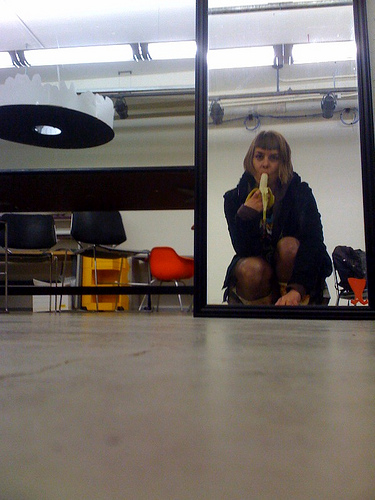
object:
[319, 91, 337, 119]
spotlight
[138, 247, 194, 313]
chair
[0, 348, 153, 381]
crack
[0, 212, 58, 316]
chair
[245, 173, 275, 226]
banana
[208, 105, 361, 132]
wires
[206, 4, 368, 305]
wall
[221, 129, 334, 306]
woman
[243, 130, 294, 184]
hair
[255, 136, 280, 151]
bangs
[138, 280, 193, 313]
legs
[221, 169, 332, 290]
coat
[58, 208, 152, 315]
chair